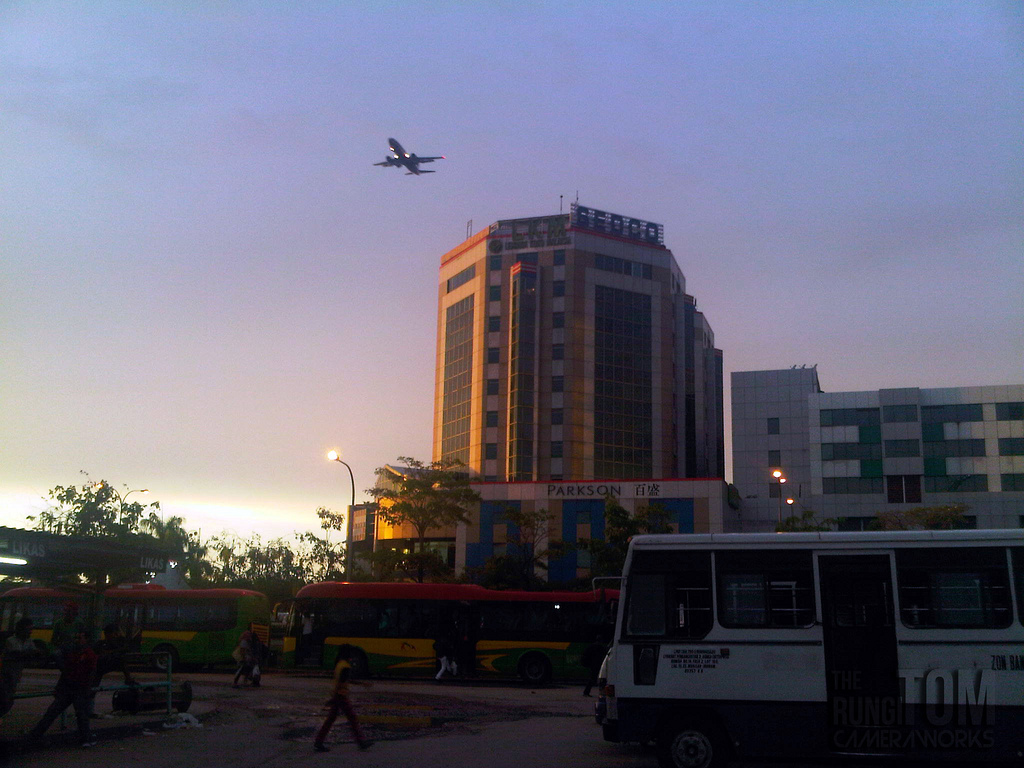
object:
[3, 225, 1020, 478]
clouds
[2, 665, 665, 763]
street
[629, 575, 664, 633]
window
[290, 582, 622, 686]
bus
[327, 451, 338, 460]
light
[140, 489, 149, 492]
leaf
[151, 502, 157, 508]
leaf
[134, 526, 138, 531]
leaf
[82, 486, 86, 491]
leaf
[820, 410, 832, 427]
window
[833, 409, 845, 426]
window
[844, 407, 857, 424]
window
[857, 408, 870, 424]
window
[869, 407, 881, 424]
window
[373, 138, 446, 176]
jet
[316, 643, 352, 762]
people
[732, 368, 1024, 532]
building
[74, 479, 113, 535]
trees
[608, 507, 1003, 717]
train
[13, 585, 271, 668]
bus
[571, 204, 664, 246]
sign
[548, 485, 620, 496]
writing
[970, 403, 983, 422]
windows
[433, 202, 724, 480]
building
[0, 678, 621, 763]
street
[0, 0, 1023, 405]
background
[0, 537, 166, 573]
logo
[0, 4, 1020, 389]
sky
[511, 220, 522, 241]
letters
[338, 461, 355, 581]
pole